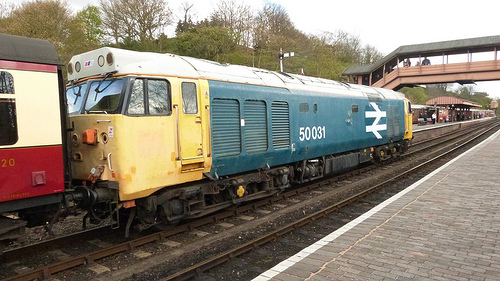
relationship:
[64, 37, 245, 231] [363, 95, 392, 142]
train a company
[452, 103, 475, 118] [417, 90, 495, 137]
passengers waiting at depot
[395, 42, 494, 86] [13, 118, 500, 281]
bridge over railroad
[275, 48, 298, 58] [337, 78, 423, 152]
lights behind engine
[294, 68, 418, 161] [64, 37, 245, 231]
rear of a train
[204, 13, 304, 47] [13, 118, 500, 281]
tree tops along railroad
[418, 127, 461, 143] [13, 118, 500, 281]
brick walkway beside railroad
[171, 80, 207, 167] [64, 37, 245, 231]
door to enter train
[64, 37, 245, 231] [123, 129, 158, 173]
train and yellow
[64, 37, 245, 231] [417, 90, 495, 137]
train pulling in to station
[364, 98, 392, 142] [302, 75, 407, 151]
white lines on blue background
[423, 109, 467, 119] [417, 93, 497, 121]
people waiting on platform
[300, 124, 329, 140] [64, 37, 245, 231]
numbers on train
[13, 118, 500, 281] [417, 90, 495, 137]
railroad at station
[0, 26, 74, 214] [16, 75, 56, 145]
caboose red and white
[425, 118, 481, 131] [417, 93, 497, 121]
white stripe at edge of platform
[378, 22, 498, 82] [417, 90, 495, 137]
pedestrian overpass at station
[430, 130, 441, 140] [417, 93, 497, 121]
brick paved platform